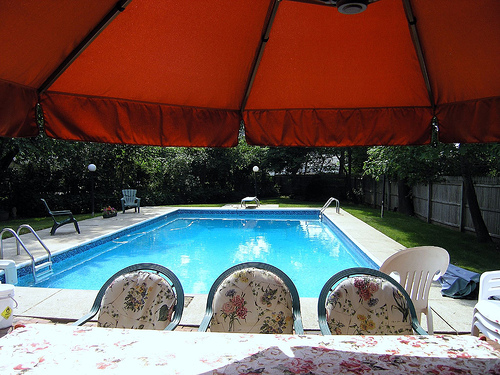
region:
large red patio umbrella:
[2, 0, 499, 164]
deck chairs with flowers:
[60, 250, 436, 352]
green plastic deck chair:
[33, 186, 89, 246]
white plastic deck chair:
[355, 226, 461, 338]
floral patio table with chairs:
[1, 245, 498, 370]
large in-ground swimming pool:
[2, 170, 455, 323]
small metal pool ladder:
[3, 215, 66, 294]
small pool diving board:
[230, 185, 270, 226]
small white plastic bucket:
[2, 272, 27, 338]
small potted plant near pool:
[93, 195, 185, 246]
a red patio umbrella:
[3, 2, 493, 152]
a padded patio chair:
[84, 265, 184, 331]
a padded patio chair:
[201, 260, 301, 330]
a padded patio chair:
[319, 262, 426, 345]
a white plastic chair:
[374, 235, 453, 337]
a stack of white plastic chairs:
[471, 262, 498, 358]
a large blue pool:
[4, 200, 383, 292]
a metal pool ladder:
[3, 217, 56, 284]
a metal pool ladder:
[314, 192, 340, 224]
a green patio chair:
[114, 187, 144, 216]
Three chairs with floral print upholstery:
[92, 260, 427, 335]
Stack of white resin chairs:
[475, 267, 498, 347]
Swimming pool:
[4, 202, 461, 338]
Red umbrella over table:
[0, 40, 498, 155]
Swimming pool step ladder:
[2, 222, 56, 281]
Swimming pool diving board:
[237, 192, 261, 212]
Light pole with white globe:
[83, 160, 99, 215]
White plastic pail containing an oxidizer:
[0, 283, 17, 333]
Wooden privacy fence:
[359, 166, 498, 237]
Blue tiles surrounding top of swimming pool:
[176, 207, 321, 221]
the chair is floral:
[345, 297, 357, 322]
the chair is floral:
[364, 310, 374, 322]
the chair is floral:
[364, 310, 376, 330]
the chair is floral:
[362, 315, 373, 330]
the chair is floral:
[351, 324, 361, 333]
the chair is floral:
[353, 294, 361, 301]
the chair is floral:
[347, 312, 362, 325]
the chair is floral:
[367, 290, 373, 310]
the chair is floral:
[349, 322, 352, 331]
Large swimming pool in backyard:
[123, 188, 418, 345]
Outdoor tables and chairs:
[98, 284, 384, 372]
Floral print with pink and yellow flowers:
[228, 274, 286, 324]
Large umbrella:
[71, 68, 483, 137]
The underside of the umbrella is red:
[51, 68, 378, 124]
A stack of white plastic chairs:
[441, 252, 494, 343]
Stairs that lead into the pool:
[10, 219, 60, 276]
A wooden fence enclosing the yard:
[388, 165, 489, 235]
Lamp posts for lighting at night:
[248, 161, 271, 194]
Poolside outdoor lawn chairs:
[111, 182, 138, 210]